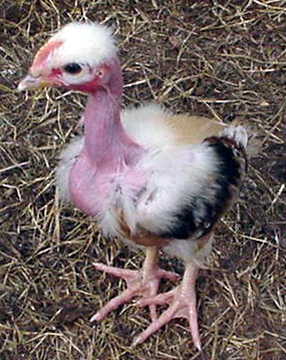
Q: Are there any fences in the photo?
A: No, there are no fences.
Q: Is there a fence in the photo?
A: No, there are no fences.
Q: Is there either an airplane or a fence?
A: No, there are no fences or airplanes.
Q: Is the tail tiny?
A: Yes, the tail is tiny.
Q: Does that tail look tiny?
A: Yes, the tail is tiny.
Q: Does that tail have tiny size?
A: Yes, the tail is tiny.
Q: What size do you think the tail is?
A: The tail is tiny.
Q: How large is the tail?
A: The tail is tiny.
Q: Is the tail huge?
A: No, the tail is tiny.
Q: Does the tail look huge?
A: No, the tail is tiny.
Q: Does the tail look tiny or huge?
A: The tail is tiny.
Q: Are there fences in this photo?
A: No, there are no fences.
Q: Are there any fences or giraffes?
A: No, there are no fences or giraffes.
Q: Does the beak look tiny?
A: Yes, the beak is tiny.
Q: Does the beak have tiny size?
A: Yes, the beak is tiny.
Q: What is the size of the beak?
A: The beak is tiny.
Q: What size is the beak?
A: The beak is tiny.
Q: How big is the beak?
A: The beak is tiny.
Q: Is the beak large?
A: No, the beak is tiny.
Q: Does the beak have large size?
A: No, the beak is tiny.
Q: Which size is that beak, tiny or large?
A: The beak is tiny.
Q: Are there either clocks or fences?
A: No, there are no fences or clocks.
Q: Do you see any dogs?
A: No, there are no dogs.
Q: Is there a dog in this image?
A: No, there are no dogs.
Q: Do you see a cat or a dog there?
A: No, there are no dogs or cats.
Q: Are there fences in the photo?
A: No, there are no fences.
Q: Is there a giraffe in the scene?
A: No, there are no giraffes.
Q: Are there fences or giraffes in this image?
A: No, there are no giraffes or fences.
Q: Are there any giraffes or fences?
A: No, there are no giraffes or fences.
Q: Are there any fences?
A: No, there are no fences.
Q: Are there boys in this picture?
A: No, there are no boys.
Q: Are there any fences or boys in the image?
A: No, there are no boys or fences.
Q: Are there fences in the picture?
A: No, there are no fences.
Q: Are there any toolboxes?
A: No, there are no toolboxes.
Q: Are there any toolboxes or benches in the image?
A: No, there are no toolboxes or benches.